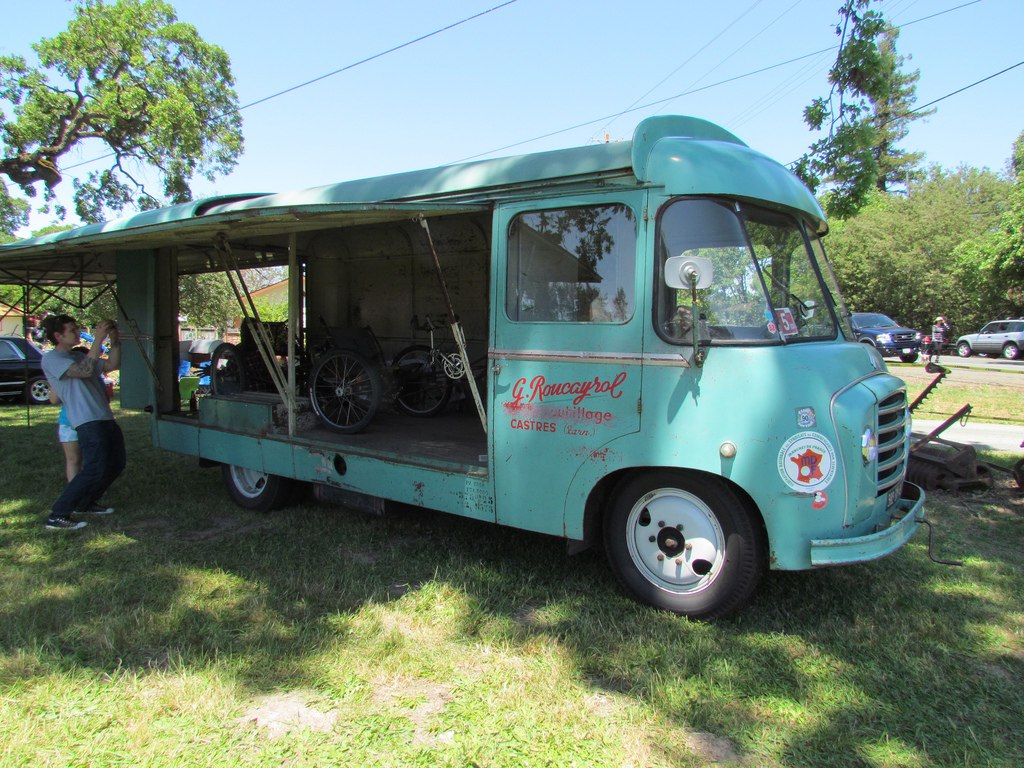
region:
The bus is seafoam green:
[15, 112, 938, 628]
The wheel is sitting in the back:
[309, 344, 392, 434]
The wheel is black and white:
[600, 466, 757, 628]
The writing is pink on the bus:
[498, 361, 634, 447]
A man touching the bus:
[26, 311, 140, 553]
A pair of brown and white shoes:
[42, 509, 88, 536]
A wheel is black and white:
[224, 456, 292, 515]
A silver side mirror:
[660, 253, 721, 295]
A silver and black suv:
[957, 320, 1021, 362]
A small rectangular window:
[505, 203, 639, 325]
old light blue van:
[147, 169, 879, 591]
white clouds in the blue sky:
[446, 33, 532, 95]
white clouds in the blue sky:
[721, 24, 772, 63]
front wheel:
[623, 492, 735, 617]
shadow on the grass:
[726, 656, 800, 701]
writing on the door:
[510, 365, 629, 441]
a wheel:
[317, 358, 374, 431]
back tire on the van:
[221, 454, 302, 506]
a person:
[47, 314, 139, 550]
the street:
[984, 422, 1022, 441]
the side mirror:
[663, 248, 718, 302]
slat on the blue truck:
[871, 397, 906, 418]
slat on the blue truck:
[870, 416, 903, 432]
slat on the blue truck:
[864, 431, 906, 452]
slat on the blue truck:
[877, 444, 903, 471]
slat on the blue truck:
[871, 464, 916, 494]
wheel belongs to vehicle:
[216, 452, 286, 520]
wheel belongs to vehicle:
[608, 468, 764, 623]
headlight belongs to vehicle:
[862, 427, 879, 476]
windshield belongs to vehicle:
[653, 193, 856, 352]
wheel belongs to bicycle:
[391, 349, 453, 422]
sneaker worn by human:
[40, 512, 89, 536]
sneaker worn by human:
[72, 498, 115, 518]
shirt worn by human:
[37, 342, 120, 425]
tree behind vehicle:
[769, 5, 932, 322]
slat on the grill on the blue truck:
[873, 390, 911, 416]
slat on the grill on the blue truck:
[877, 428, 916, 458]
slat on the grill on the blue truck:
[873, 444, 913, 470]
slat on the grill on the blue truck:
[863, 469, 905, 501]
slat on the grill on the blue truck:
[868, 441, 913, 467]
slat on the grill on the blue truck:
[873, 413, 905, 434]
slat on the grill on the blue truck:
[868, 397, 906, 416]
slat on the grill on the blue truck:
[877, 467, 904, 496]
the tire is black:
[602, 467, 748, 617]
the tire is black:
[225, 457, 296, 511]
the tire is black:
[26, 378, 56, 401]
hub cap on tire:
[229, 463, 265, 495]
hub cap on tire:
[36, 378, 53, 401]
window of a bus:
[658, 191, 776, 348]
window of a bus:
[740, 198, 826, 342]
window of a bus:
[807, 216, 850, 337]